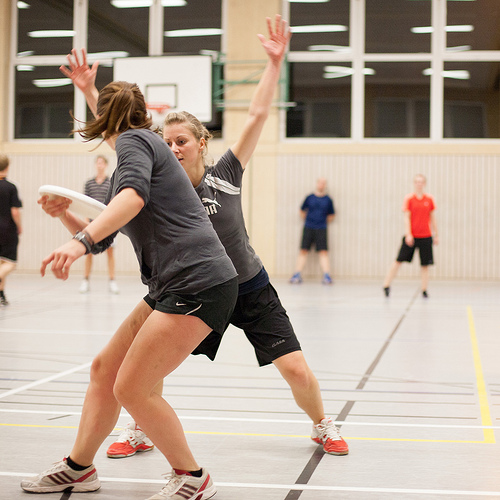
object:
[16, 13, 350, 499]
two girls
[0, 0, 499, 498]
court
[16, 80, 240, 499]
girl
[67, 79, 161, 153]
brown hair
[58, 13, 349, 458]
girl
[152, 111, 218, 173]
blond hair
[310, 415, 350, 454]
red shoes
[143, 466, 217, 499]
shoes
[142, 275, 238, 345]
black shorts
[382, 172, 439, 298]
girl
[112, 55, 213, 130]
basketball hoop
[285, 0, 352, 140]
gymnasium window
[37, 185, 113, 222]
frisbee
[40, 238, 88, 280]
left hand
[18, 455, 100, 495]
left shoe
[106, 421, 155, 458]
red shoe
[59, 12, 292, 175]
hands extended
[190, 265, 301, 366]
black shorts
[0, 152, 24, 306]
woman